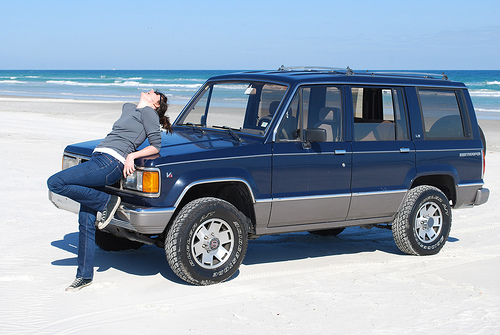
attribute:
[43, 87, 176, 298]
woman — leaning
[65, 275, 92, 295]
shoe — black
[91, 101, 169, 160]
shirt — gray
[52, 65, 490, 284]
car — blue, gray, suv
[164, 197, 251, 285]
wheel — tire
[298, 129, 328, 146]
mirror — side view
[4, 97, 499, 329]
beach — sand, white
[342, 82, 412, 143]
window — down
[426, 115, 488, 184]
spare tire — on trunk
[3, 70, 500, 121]
water — ocean, blue